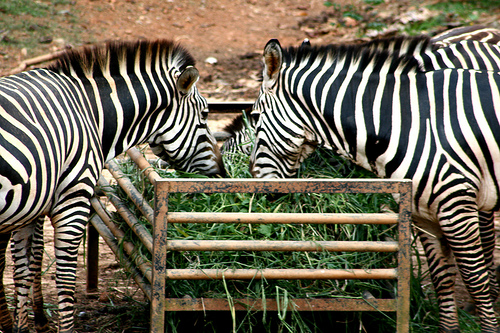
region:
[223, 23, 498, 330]
Three zebras to the right of two more.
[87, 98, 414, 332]
An old worn brown feeding crate for zebras.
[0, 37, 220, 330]
Two zebras on the left of the others.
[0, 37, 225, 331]
A zebra on the left with black and white stripes.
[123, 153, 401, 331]
Green grass in the metal crate.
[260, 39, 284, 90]
The left ear of a black and white ear of a left side zebra.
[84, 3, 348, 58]
Brown dirt ground above zebras.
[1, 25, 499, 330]
All the black and white zebras eating.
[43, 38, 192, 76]
Black and white zebra mane on the left zebra.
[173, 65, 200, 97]
Ear on the zebra to the left of the others.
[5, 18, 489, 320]
zebras feeding from square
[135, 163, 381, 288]
green plants in feeding square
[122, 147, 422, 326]
feeding square of metal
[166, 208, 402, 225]
bar on the feeding square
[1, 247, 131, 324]
ground zebras stand on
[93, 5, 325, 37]
ground in distance from zebras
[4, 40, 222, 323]
zebra feeding on side alone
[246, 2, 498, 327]
group of zebras feeding on side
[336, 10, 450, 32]
green plant growing on ground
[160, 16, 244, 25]
rocks on the ground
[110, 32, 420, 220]
two zebras eating grass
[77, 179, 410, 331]
a metal feeding troft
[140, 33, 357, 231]
two zebra's with their heads in a troft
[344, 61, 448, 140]
black and white stripes on a zebra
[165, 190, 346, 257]
green grass in a feeding troft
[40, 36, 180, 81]
the black and a white maine on a zebra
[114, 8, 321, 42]
red gravel on the ground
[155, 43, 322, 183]
two zebra's facing each other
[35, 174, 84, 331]
a striped leg on a zebra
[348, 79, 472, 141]
a striped pattern on a zebra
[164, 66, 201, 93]
an ear of a zebra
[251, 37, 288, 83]
an ear of a zebra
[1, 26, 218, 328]
a zebra that is eating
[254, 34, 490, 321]
a zebra that is eating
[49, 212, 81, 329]
the leg of a zebra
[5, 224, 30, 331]
the leg of a zebra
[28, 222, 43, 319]
the leg of a zebra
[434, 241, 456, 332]
the leg of a zebra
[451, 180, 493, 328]
the leg of a zebra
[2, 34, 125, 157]
black and white zebra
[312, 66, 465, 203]
black and white zebra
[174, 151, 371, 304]
grass in wooden fence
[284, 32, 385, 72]
thick mane on zebra's neck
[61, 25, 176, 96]
thick mane on zebra's neck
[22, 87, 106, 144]
white and black stripes on zebra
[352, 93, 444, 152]
white and black stripes on zebra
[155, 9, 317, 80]
dirt path near zebras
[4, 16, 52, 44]
short grass growing on ground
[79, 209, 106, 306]
wooden legs of feeding area